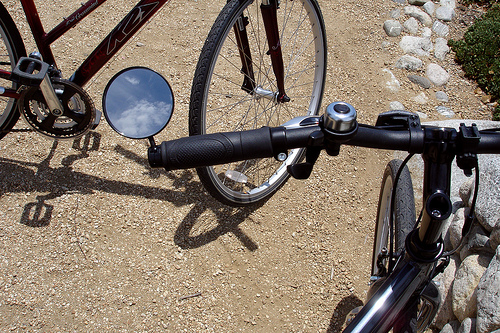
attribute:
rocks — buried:
[396, 32, 458, 98]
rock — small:
[385, 59, 425, 97]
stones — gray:
[383, 1, 455, 110]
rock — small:
[373, 0, 480, 107]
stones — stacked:
[465, 154, 495, 319]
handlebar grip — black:
[138, 130, 286, 165]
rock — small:
[379, 0, 497, 110]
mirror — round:
[100, 65, 175, 139]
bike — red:
[101, 65, 498, 332]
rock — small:
[383, 36, 430, 73]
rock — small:
[46, 254, 73, 278]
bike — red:
[6, 4, 329, 209]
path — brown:
[376, 2, 459, 113]